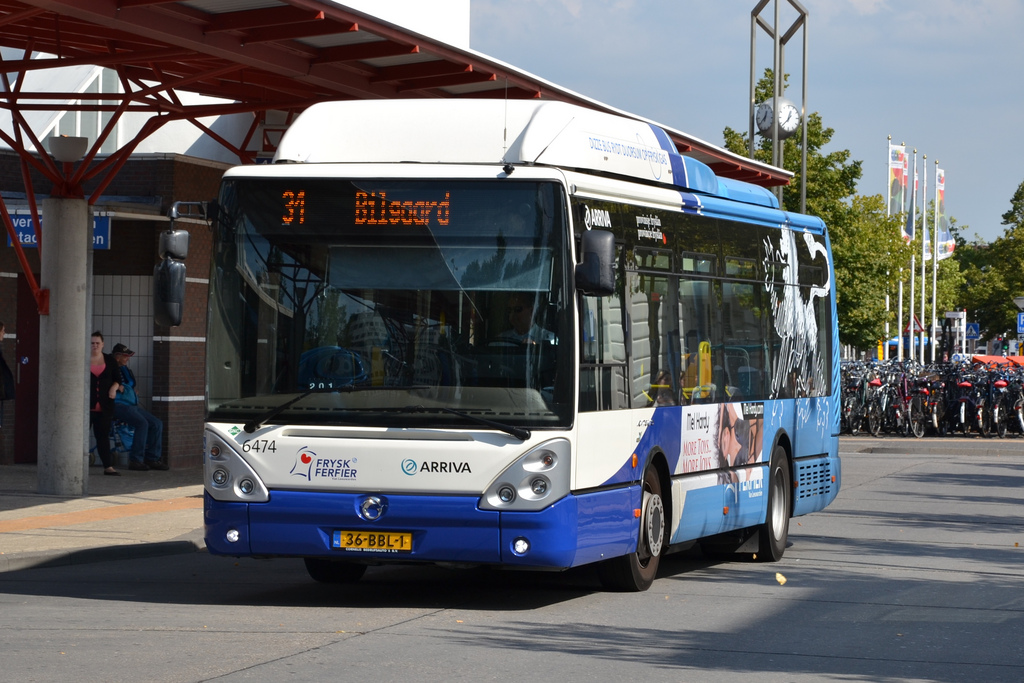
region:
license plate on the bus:
[331, 522, 405, 551]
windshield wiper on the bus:
[223, 363, 351, 439]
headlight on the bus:
[470, 452, 575, 545]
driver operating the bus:
[460, 284, 566, 374]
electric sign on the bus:
[243, 168, 472, 242]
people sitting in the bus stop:
[79, 319, 165, 468]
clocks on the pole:
[742, 100, 816, 139]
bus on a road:
[203, 88, 951, 674]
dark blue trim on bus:
[189, 464, 686, 592]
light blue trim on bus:
[654, 154, 841, 540]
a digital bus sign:
[238, 187, 472, 245]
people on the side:
[69, 310, 169, 520]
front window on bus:
[215, 177, 583, 434]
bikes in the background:
[821, 328, 1022, 440]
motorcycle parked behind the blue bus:
[984, 362, 1016, 427]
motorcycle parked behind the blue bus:
[950, 356, 970, 445]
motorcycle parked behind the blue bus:
[908, 340, 935, 421]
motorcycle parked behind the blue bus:
[835, 349, 864, 439]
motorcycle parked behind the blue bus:
[889, 355, 924, 439]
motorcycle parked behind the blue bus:
[934, 349, 955, 427]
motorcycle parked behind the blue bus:
[895, 346, 944, 432]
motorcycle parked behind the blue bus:
[845, 350, 888, 436]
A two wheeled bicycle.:
[904, 370, 934, 437]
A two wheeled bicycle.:
[950, 367, 986, 429]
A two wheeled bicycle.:
[982, 362, 998, 424]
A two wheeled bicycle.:
[890, 370, 917, 424]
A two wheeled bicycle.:
[868, 361, 884, 423]